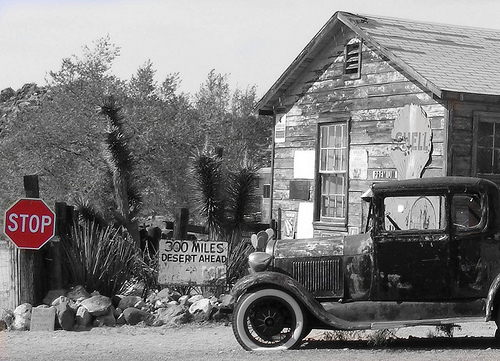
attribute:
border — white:
[48, 207, 58, 237]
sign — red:
[6, 191, 53, 248]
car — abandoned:
[269, 181, 483, 359]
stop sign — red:
[1, 193, 58, 253]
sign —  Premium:
[331, 139, 462, 204]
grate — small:
[278, 253, 345, 295]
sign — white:
[153, 235, 231, 290]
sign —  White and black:
[156, 239, 229, 286]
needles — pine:
[95, 92, 142, 217]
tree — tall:
[16, 34, 153, 225]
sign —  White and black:
[132, 217, 253, 292]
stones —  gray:
[195, 300, 206, 316]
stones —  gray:
[172, 300, 188, 327]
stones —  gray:
[125, 306, 147, 323]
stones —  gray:
[87, 293, 109, 308]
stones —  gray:
[157, 290, 168, 302]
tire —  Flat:
[222, 279, 305, 356]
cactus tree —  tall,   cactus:
[98, 94, 143, 223]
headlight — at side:
[247, 250, 270, 270]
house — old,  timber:
[236, 14, 491, 264]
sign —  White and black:
[154, 239, 236, 285]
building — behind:
[230, 1, 498, 305]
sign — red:
[2, 194, 61, 259]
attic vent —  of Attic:
[344, 39, 359, 79]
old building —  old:
[248, 9, 498, 236]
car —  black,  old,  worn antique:
[228, 177, 498, 359]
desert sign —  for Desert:
[155, 239, 229, 286]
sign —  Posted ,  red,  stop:
[4, 197, 56, 250]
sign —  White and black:
[161, 239, 231, 288]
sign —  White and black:
[160, 235, 228, 287]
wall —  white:
[251, 287, 278, 293]